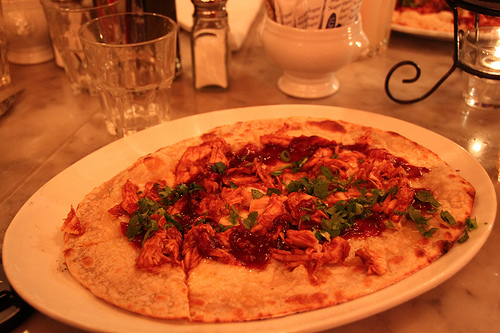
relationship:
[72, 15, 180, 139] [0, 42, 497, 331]
glass on table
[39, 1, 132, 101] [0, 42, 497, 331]
glass on table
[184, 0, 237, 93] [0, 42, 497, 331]
salt on table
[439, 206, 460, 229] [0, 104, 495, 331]
vegetable on plate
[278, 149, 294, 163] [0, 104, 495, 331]
vegetable on plate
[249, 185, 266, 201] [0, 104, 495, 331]
vegetable on plate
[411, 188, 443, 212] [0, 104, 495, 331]
vegetable on plate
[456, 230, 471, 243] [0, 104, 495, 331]
vegetable on plate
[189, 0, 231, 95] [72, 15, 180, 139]
shaker made of glass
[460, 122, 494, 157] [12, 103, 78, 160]
reflection on table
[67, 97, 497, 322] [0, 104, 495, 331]
pizza on plate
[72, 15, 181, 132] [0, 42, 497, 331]
glass sitting on table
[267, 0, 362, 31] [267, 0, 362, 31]
sugar in sugar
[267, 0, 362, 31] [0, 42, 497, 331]
sugar on table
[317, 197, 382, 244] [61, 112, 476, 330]
herb on top of pizza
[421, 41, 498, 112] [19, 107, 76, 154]
candle on table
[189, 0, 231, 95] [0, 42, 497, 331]
shaker on table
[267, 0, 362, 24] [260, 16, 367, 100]
sugar in cup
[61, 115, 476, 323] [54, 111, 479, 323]
pizza main food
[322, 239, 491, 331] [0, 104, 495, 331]
edge of plate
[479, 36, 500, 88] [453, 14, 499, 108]
candle in glass holder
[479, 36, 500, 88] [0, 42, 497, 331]
candle on table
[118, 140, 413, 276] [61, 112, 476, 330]
shredded meat on top of pizza